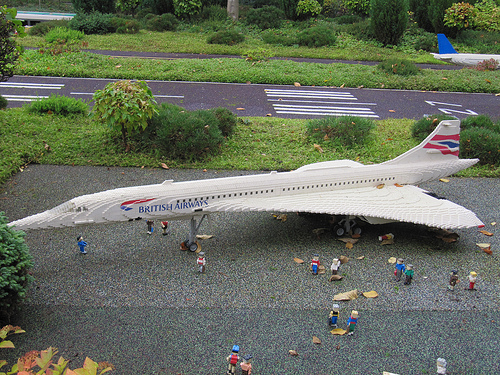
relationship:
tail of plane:
[435, 33, 463, 56] [248, 178, 490, 258]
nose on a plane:
[1, 203, 56, 265] [3, 113, 489, 246]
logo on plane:
[138, 199, 208, 213] [5, 120, 485, 230]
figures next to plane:
[249, 244, 484, 341] [25, 136, 499, 290]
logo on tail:
[425, 120, 467, 170] [402, 106, 483, 184]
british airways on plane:
[135, 199, 213, 215] [3, 113, 489, 246]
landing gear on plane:
[173, 211, 212, 254] [38, 115, 474, 280]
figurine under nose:
[64, 231, 97, 262] [0, 207, 55, 234]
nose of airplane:
[0, 207, 55, 234] [3, 111, 487, 254]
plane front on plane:
[3, 185, 144, 236] [3, 113, 489, 246]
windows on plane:
[399, 164, 496, 205] [3, 113, 489, 246]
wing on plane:
[212, 186, 487, 232] [3, 113, 489, 246]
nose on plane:
[0, 207, 55, 234] [3, 113, 489, 246]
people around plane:
[300, 241, 423, 340] [25, 138, 492, 271]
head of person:
[404, 262, 418, 272] [400, 259, 415, 286]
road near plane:
[3, 64, 498, 136] [7, 114, 492, 275]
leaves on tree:
[85, 76, 152, 122] [97, 78, 154, 152]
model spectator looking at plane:
[348, 310, 358, 333] [5, 120, 485, 230]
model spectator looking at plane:
[329, 302, 339, 325] [5, 120, 485, 230]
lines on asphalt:
[272, 106, 350, 113] [206, 85, 241, 106]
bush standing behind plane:
[90, 79, 155, 149] [3, 113, 489, 246]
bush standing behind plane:
[157, 106, 223, 162] [3, 113, 489, 246]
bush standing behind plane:
[208, 105, 238, 133] [3, 113, 489, 246]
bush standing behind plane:
[25, 91, 88, 113] [3, 113, 489, 246]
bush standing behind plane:
[148, 94, 182, 135] [3, 113, 489, 246]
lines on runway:
[232, 57, 477, 129] [2, 69, 497, 137]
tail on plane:
[428, 27, 494, 74] [422, 25, 498, 75]